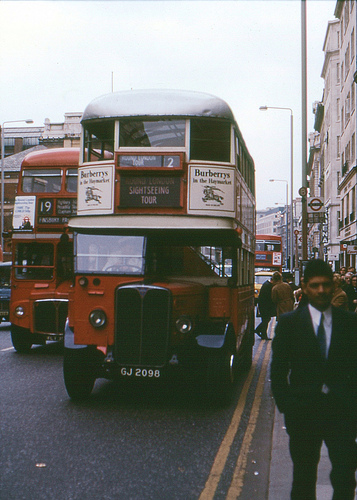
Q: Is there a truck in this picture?
A: No, there are no trucks.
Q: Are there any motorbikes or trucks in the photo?
A: No, there are no trucks or motorbikes.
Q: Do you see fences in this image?
A: No, there are no fences.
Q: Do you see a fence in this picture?
A: No, there are no fences.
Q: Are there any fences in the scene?
A: No, there are no fences.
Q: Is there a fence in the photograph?
A: No, there are no fences.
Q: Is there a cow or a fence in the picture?
A: No, there are no fences or cows.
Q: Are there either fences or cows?
A: No, there are no fences or cows.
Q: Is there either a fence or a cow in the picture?
A: No, there are no fences or cows.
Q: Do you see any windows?
A: Yes, there is a window.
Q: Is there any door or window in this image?
A: Yes, there is a window.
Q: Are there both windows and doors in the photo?
A: No, there is a window but no doors.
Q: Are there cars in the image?
A: No, there are no cars.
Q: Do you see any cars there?
A: No, there are no cars.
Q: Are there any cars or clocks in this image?
A: No, there are no cars or clocks.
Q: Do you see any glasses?
A: No, there are no glasses.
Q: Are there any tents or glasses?
A: No, there are no glasses or tents.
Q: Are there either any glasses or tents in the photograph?
A: No, there are no glasses or tents.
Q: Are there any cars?
A: No, there are no cars.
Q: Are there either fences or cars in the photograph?
A: No, there are no cars or fences.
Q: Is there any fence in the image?
A: No, there are no fences.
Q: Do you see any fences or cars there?
A: No, there are no fences or cars.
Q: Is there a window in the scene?
A: Yes, there is a window.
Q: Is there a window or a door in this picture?
A: Yes, there is a window.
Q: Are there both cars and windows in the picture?
A: No, there is a window but no cars.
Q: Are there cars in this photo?
A: No, there are no cars.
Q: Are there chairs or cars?
A: No, there are no cars or chairs.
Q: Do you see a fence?
A: No, there are no fences.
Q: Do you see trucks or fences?
A: No, there are no fences or trucks.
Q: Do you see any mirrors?
A: No, there are no mirrors.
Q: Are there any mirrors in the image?
A: No, there are no mirrors.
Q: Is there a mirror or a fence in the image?
A: No, there are no mirrors or fences.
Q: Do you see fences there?
A: No, there are no fences.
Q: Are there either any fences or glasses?
A: No, there are no fences or glasses.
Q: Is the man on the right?
A: Yes, the man is on the right of the image.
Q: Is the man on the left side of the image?
A: No, the man is on the right of the image.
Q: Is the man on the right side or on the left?
A: The man is on the right of the image.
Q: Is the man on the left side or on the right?
A: The man is on the right of the image.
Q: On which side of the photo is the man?
A: The man is on the right of the image.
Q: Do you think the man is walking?
A: Yes, the man is walking.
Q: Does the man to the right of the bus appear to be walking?
A: Yes, the man is walking.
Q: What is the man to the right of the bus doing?
A: The man is walking.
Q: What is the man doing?
A: The man is walking.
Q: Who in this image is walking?
A: The man is walking.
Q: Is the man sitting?
A: No, the man is walking.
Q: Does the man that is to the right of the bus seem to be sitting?
A: No, the man is walking.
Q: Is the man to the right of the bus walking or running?
A: The man is walking.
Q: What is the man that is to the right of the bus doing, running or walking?
A: The man is walking.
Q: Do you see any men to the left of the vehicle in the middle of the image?
A: No, the man is to the right of the bus.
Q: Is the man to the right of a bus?
A: Yes, the man is to the right of a bus.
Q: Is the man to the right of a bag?
A: No, the man is to the right of a bus.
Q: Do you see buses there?
A: Yes, there is a bus.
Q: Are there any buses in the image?
A: Yes, there is a bus.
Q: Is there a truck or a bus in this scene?
A: Yes, there is a bus.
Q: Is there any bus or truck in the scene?
A: Yes, there is a bus.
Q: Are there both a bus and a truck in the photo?
A: No, there is a bus but no trucks.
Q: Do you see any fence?
A: No, there are no fences.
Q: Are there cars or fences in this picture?
A: No, there are no fences or cars.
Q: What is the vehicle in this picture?
A: The vehicle is a bus.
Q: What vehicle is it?
A: The vehicle is a bus.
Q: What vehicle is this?
A: This is a bus.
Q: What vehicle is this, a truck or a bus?
A: This is a bus.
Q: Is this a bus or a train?
A: This is a bus.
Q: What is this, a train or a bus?
A: This is a bus.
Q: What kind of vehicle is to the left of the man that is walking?
A: The vehicle is a bus.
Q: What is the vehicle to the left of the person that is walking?
A: The vehicle is a bus.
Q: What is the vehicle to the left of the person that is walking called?
A: The vehicle is a bus.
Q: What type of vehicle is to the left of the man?
A: The vehicle is a bus.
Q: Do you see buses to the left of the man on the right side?
A: Yes, there is a bus to the left of the man.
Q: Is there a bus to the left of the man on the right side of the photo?
A: Yes, there is a bus to the left of the man.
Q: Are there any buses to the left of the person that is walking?
A: Yes, there is a bus to the left of the man.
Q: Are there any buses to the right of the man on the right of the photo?
A: No, the bus is to the left of the man.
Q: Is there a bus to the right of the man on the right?
A: No, the bus is to the left of the man.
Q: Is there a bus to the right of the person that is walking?
A: No, the bus is to the left of the man.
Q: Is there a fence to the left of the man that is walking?
A: No, there is a bus to the left of the man.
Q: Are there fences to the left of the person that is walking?
A: No, there is a bus to the left of the man.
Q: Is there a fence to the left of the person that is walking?
A: No, there is a bus to the left of the man.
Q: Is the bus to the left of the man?
A: Yes, the bus is to the left of the man.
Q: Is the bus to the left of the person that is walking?
A: Yes, the bus is to the left of the man.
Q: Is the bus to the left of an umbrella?
A: No, the bus is to the left of the man.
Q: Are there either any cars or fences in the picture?
A: No, there are no cars or fences.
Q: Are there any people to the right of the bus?
A: Yes, there are people to the right of the bus.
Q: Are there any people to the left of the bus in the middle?
A: No, the people are to the right of the bus.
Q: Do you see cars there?
A: No, there are no cars.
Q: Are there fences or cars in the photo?
A: No, there are no cars or fences.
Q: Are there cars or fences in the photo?
A: No, there are no cars or fences.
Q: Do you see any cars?
A: No, there are no cars.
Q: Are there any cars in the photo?
A: No, there are no cars.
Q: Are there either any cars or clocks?
A: No, there are no cars or clocks.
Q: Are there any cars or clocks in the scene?
A: No, there are no cars or clocks.